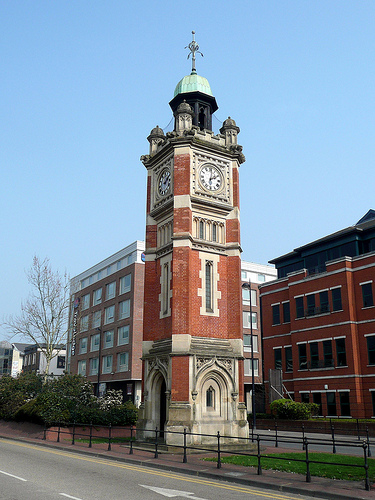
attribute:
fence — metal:
[40, 419, 371, 494]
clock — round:
[189, 149, 234, 211]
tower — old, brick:
[132, 30, 251, 448]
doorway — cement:
[140, 349, 168, 444]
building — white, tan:
[62, 239, 276, 417]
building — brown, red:
[259, 251, 374, 420]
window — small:
[210, 218, 220, 243]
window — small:
[198, 218, 208, 241]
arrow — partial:
[136, 483, 211, 499]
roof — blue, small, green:
[167, 76, 215, 101]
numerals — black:
[199, 168, 222, 193]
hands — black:
[163, 174, 173, 189]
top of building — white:
[67, 240, 276, 294]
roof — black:
[266, 208, 374, 268]